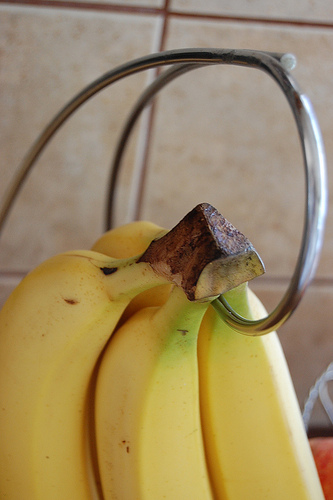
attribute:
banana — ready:
[200, 276, 325, 498]